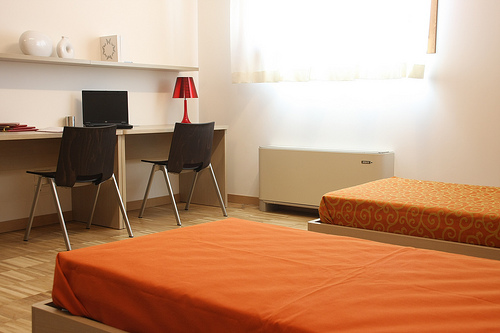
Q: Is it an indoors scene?
A: Yes, it is indoors.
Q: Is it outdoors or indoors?
A: It is indoors.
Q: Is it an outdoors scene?
A: No, it is indoors.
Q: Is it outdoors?
A: No, it is indoors.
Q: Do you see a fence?
A: No, there are no fences.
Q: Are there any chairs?
A: Yes, there is a chair.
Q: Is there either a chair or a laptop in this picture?
A: Yes, there is a chair.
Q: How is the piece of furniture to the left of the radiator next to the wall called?
A: The piece of furniture is a chair.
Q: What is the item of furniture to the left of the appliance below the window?
A: The piece of furniture is a chair.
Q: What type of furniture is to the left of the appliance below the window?
A: The piece of furniture is a chair.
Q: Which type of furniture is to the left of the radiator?
A: The piece of furniture is a chair.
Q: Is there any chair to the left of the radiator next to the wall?
A: Yes, there is a chair to the left of the radiator.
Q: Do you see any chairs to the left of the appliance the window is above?
A: Yes, there is a chair to the left of the radiator.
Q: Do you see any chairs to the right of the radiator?
A: No, the chair is to the left of the radiator.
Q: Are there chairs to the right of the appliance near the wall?
A: No, the chair is to the left of the radiator.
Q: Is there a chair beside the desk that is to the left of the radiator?
A: Yes, there is a chair beside the desk.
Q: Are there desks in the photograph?
A: Yes, there is a desk.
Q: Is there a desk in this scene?
A: Yes, there is a desk.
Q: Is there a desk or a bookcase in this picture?
A: Yes, there is a desk.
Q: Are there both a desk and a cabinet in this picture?
A: No, there is a desk but no cabinets.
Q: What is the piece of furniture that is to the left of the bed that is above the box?
A: The piece of furniture is a desk.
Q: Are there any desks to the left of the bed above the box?
A: Yes, there is a desk to the left of the bed.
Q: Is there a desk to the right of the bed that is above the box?
A: No, the desk is to the left of the bed.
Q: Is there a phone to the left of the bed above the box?
A: No, there is a desk to the left of the bed.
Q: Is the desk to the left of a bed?
A: Yes, the desk is to the left of a bed.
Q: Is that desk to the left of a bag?
A: No, the desk is to the left of a bed.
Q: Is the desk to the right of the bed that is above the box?
A: No, the desk is to the left of the bed.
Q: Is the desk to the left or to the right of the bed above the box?
A: The desk is to the left of the bed.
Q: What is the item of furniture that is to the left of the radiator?
A: The piece of furniture is a desk.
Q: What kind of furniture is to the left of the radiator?
A: The piece of furniture is a desk.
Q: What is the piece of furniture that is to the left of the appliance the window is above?
A: The piece of furniture is a desk.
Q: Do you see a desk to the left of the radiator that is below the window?
A: Yes, there is a desk to the left of the radiator.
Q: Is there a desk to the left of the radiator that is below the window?
A: Yes, there is a desk to the left of the radiator.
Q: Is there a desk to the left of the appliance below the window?
A: Yes, there is a desk to the left of the radiator.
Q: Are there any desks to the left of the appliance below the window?
A: Yes, there is a desk to the left of the radiator.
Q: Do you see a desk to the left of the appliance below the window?
A: Yes, there is a desk to the left of the radiator.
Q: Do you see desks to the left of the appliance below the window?
A: Yes, there is a desk to the left of the radiator.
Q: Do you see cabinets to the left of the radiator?
A: No, there is a desk to the left of the radiator.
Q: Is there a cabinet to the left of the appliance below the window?
A: No, there is a desk to the left of the radiator.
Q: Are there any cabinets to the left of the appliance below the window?
A: No, there is a desk to the left of the radiator.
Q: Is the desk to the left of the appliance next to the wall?
A: Yes, the desk is to the left of the radiator.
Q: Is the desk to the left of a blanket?
A: No, the desk is to the left of the radiator.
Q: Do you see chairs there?
A: Yes, there is a chair.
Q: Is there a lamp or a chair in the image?
A: Yes, there is a chair.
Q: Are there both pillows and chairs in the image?
A: No, there is a chair but no pillows.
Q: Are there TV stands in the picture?
A: No, there are no TV stands.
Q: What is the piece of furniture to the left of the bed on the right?
A: The piece of furniture is a chair.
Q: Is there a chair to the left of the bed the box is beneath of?
A: Yes, there is a chair to the left of the bed.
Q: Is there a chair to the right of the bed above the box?
A: No, the chair is to the left of the bed.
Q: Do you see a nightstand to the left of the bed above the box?
A: No, there is a chair to the left of the bed.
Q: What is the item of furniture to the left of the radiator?
A: The piece of furniture is a chair.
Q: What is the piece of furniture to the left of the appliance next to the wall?
A: The piece of furniture is a chair.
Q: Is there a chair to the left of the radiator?
A: Yes, there is a chair to the left of the radiator.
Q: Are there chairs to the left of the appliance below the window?
A: Yes, there is a chair to the left of the radiator.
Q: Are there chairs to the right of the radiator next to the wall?
A: No, the chair is to the left of the radiator.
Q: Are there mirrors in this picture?
A: No, there are no mirrors.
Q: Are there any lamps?
A: Yes, there is a lamp.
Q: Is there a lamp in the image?
A: Yes, there is a lamp.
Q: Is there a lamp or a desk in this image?
A: Yes, there is a lamp.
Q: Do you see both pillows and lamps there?
A: No, there is a lamp but no pillows.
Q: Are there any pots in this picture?
A: No, there are no pots.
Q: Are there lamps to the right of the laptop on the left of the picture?
A: Yes, there is a lamp to the right of the laptop.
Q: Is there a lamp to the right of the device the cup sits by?
A: Yes, there is a lamp to the right of the laptop.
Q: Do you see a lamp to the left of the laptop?
A: No, the lamp is to the right of the laptop.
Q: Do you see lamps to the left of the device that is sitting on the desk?
A: No, the lamp is to the right of the laptop.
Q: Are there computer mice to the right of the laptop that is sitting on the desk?
A: No, there is a lamp to the right of the laptop.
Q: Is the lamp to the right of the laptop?
A: Yes, the lamp is to the right of the laptop.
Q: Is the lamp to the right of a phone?
A: No, the lamp is to the right of the laptop.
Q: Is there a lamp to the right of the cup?
A: Yes, there is a lamp to the right of the cup.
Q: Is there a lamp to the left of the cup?
A: No, the lamp is to the right of the cup.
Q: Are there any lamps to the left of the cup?
A: No, the lamp is to the right of the cup.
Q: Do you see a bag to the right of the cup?
A: No, there is a lamp to the right of the cup.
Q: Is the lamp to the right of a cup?
A: Yes, the lamp is to the right of a cup.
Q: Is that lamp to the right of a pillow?
A: No, the lamp is to the right of a cup.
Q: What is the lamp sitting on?
A: The lamp is sitting on the desk.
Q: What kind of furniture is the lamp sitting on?
A: The lamp is sitting on the desk.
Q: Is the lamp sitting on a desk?
A: Yes, the lamp is sitting on a desk.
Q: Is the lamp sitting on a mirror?
A: No, the lamp is sitting on a desk.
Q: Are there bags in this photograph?
A: No, there are no bags.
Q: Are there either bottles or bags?
A: No, there are no bags or bottles.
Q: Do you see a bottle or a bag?
A: No, there are no bags or bottles.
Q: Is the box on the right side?
A: Yes, the box is on the right of the image.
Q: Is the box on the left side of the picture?
A: No, the box is on the right of the image.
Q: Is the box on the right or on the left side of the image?
A: The box is on the right of the image.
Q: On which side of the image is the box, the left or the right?
A: The box is on the right of the image.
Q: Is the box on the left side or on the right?
A: The box is on the right of the image.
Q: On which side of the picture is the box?
A: The box is on the right of the image.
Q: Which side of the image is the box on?
A: The box is on the right of the image.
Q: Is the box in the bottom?
A: Yes, the box is in the bottom of the image.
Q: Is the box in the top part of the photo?
A: No, the box is in the bottom of the image.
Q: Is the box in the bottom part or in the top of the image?
A: The box is in the bottom of the image.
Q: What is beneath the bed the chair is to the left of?
A: The box is beneath the bed.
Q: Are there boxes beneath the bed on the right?
A: Yes, there is a box beneath the bed.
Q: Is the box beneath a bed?
A: Yes, the box is beneath a bed.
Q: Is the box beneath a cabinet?
A: No, the box is beneath a bed.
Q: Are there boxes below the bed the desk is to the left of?
A: Yes, there is a box below the bed.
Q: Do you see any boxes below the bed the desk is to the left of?
A: Yes, there is a box below the bed.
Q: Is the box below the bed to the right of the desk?
A: Yes, the box is below the bed.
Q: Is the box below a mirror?
A: No, the box is below the bed.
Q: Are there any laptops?
A: Yes, there is a laptop.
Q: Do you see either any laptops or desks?
A: Yes, there is a laptop.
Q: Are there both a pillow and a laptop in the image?
A: No, there is a laptop but no pillows.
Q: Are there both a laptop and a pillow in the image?
A: No, there is a laptop but no pillows.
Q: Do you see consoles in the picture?
A: No, there are no consoles.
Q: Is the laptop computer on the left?
A: Yes, the laptop computer is on the left of the image.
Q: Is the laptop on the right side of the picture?
A: No, the laptop is on the left of the image.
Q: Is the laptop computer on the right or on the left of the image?
A: The laptop computer is on the left of the image.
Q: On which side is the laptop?
A: The laptop is on the left of the image.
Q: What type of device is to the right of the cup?
A: The device is a laptop.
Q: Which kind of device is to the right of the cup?
A: The device is a laptop.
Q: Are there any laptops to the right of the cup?
A: Yes, there is a laptop to the right of the cup.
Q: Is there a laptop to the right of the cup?
A: Yes, there is a laptop to the right of the cup.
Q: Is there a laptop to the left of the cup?
A: No, the laptop is to the right of the cup.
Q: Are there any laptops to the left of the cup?
A: No, the laptop is to the right of the cup.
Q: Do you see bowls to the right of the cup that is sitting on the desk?
A: No, there is a laptop to the right of the cup.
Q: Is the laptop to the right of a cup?
A: Yes, the laptop is to the right of a cup.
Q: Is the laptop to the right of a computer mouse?
A: No, the laptop is to the right of a cup.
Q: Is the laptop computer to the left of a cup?
A: No, the laptop computer is to the right of a cup.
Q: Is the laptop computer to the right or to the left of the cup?
A: The laptop computer is to the right of the cup.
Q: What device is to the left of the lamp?
A: The device is a laptop.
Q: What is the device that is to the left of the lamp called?
A: The device is a laptop.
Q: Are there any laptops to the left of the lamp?
A: Yes, there is a laptop to the left of the lamp.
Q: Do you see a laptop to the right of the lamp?
A: No, the laptop is to the left of the lamp.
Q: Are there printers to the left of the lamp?
A: No, there is a laptop to the left of the lamp.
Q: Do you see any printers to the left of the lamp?
A: No, there is a laptop to the left of the lamp.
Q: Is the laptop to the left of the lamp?
A: Yes, the laptop is to the left of the lamp.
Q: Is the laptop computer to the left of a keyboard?
A: No, the laptop computer is to the left of the lamp.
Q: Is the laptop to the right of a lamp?
A: No, the laptop is to the left of a lamp.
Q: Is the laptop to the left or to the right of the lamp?
A: The laptop is to the left of the lamp.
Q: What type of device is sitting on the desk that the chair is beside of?
A: The device is a laptop.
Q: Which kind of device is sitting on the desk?
A: The device is a laptop.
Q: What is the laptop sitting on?
A: The laptop is sitting on the desk.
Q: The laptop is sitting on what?
A: The laptop is sitting on the desk.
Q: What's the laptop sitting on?
A: The laptop is sitting on the desk.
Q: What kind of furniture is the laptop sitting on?
A: The laptop is sitting on the desk.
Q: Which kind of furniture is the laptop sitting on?
A: The laptop is sitting on the desk.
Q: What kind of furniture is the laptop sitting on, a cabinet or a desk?
A: The laptop is sitting on a desk.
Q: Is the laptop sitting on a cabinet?
A: No, the laptop is sitting on a desk.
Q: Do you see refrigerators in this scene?
A: No, there are no refrigerators.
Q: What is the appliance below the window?
A: The appliance is a radiator.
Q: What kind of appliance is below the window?
A: The appliance is a radiator.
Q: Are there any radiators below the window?
A: Yes, there is a radiator below the window.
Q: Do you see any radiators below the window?
A: Yes, there is a radiator below the window.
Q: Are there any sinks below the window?
A: No, there is a radiator below the window.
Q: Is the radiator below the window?
A: Yes, the radiator is below the window.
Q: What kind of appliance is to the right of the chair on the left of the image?
A: The appliance is a radiator.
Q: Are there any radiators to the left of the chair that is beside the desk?
A: No, the radiator is to the right of the chair.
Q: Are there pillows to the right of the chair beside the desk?
A: No, there is a radiator to the right of the chair.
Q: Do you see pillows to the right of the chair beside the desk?
A: No, there is a radiator to the right of the chair.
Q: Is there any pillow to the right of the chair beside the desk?
A: No, there is a radiator to the right of the chair.